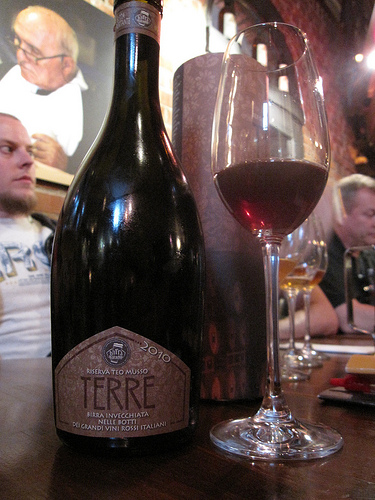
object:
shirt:
[312, 228, 375, 311]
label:
[54, 325, 191, 440]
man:
[1, 112, 52, 361]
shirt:
[0, 218, 55, 359]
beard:
[0, 192, 40, 215]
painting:
[1, 0, 127, 184]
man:
[0, 5, 95, 176]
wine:
[212, 160, 330, 249]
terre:
[80, 375, 156, 409]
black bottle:
[51, 0, 208, 456]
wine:
[50, 0, 207, 458]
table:
[0, 339, 375, 499]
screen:
[0, 0, 111, 77]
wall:
[0, 0, 375, 210]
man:
[317, 173, 375, 337]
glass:
[208, 20, 345, 463]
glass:
[279, 209, 311, 384]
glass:
[279, 212, 323, 367]